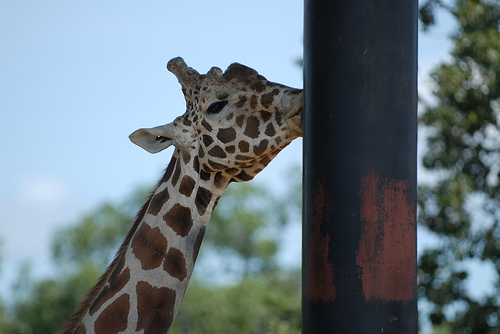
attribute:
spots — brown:
[115, 221, 207, 330]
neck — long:
[83, 154, 202, 291]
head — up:
[177, 47, 296, 149]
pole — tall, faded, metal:
[296, 12, 421, 322]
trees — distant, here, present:
[216, 209, 270, 241]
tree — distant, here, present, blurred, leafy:
[427, 37, 494, 199]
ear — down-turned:
[126, 116, 229, 175]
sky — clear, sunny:
[28, 40, 205, 152]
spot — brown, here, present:
[161, 203, 197, 242]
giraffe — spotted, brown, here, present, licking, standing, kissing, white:
[64, 55, 303, 333]